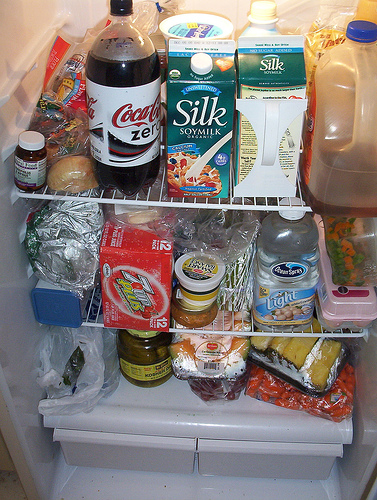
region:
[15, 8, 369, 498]
Picture is taken in fridge.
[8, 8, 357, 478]
Fridge is white color.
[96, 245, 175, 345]
7up Box is red color.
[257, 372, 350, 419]
Baby carrot is orange color.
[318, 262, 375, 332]
Egg case is white color.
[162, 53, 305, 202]
two can of soys milk in top rack.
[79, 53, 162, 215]
Coca cola bottle is in top rack.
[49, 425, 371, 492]
Two white box is in bottom.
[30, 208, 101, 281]
Foil bag is silver color.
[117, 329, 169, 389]
Pickle is in the bottom rack.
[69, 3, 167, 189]
a bottle of cola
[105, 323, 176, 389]
a jar of pickles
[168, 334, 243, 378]
a package of cantaloupe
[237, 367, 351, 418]
a bag of carrots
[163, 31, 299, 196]
2 cartons of soy milk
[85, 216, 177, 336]
a 12 pack of soda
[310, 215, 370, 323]
a carton of eggs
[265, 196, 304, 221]
the bottle cap is white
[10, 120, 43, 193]
a bottle of pills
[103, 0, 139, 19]
the bottle cap is black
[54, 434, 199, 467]
the white drawer on the left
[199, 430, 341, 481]
the white drawer on the right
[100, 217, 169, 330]
the red 7up plus box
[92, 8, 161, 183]
the coca cola zero bottle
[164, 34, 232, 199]
the silk soymilk carton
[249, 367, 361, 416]
the bag of carrots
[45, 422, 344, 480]
the two drawers on the bottom of the fridge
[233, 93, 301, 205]
the white plastic handle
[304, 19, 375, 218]
the plastic tea jug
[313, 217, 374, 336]
the egg carton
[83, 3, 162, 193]
two liter bottle of coke zero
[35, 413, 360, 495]
two white crisper drawers in fridge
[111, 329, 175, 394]
jar of green pickles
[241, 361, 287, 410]
a bag of baby carrots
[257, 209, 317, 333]
a bottle of oceanspray juice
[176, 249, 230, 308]
a yellow and white container of margarine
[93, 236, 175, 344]
a twelve pack of 7 UP plus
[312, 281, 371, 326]
a pink carton of eggs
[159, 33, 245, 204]
a carton of silk soymikk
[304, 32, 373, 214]
a gallon of chocolate milk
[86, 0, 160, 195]
a plastic bottle of Coca Cola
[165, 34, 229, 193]
a carton of soy milk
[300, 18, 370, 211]
a plastic bottle of juice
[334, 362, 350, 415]
a bag of baby carrots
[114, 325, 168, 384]
a bottle of kosher pickles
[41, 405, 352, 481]
the refrigerator vegetable drawers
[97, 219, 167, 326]
a box of 7up soda cans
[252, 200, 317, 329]
a plastic bottle of cranberry juice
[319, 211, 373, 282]
a bag of mixed vegetables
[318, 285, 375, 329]
a Styrofoam pack of a dozen eggs